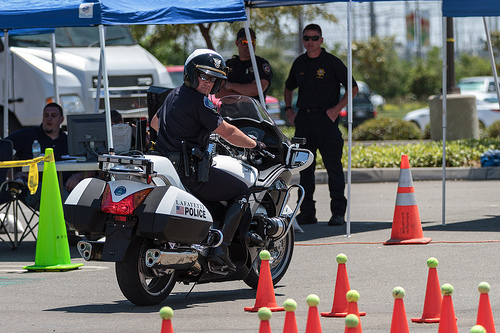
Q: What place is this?
A: It is a parking lot.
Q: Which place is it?
A: It is a parking lot.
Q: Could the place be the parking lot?
A: Yes, it is the parking lot.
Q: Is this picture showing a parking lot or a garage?
A: It is showing a parking lot.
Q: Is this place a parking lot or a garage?
A: It is a parking lot.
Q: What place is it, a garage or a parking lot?
A: It is a parking lot.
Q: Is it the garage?
A: No, it is the parking lot.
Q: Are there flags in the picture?
A: No, there are no flags.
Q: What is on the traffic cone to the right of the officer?
A: The tape is on the safety cone.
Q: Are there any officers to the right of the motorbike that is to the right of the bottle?
A: Yes, there is an officer to the right of the motorbike.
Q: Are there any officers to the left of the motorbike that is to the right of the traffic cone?
A: No, the officer is to the right of the motorbike.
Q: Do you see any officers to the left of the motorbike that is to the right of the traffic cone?
A: No, the officer is to the right of the motorbike.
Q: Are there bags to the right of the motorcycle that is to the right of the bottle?
A: No, there is an officer to the right of the motorbike.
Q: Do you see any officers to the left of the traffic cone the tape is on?
A: Yes, there is an officer to the left of the safety cone.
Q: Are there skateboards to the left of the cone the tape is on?
A: No, there is an officer to the left of the cone.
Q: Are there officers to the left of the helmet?
A: No, the officer is to the right of the helmet.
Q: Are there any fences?
A: No, there are no fences.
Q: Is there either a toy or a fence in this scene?
A: No, there are no fences or toys.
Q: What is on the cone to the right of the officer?
A: The tape is on the traffic cone.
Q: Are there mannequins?
A: No, there are no mannequins.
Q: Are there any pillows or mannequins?
A: No, there are no mannequins or pillows.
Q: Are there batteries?
A: No, there are no batteries.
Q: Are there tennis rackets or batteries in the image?
A: No, there are no batteries or tennis rackets.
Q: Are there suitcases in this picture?
A: No, there are no suitcases.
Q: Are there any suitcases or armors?
A: No, there are no suitcases or armors.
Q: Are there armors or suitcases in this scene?
A: No, there are no suitcases or armors.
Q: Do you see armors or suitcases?
A: No, there are no suitcases or armors.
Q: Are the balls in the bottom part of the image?
A: Yes, the balls are in the bottom of the image.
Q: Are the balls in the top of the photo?
A: No, the balls are in the bottom of the image.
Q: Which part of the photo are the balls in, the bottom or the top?
A: The balls are in the bottom of the image.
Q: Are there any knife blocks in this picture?
A: No, there are no knife blocks.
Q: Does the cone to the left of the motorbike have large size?
A: Yes, the cone is large.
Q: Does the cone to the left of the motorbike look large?
A: Yes, the cone is large.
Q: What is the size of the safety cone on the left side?
A: The cone is large.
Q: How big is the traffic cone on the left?
A: The cone is large.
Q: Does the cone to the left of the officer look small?
A: No, the traffic cone is large.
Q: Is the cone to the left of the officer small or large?
A: The traffic cone is large.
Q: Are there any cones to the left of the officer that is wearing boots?
A: Yes, there is a cone to the left of the officer.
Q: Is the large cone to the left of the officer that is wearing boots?
A: Yes, the traffic cone is to the left of the officer.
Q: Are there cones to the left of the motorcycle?
A: Yes, there is a cone to the left of the motorcycle.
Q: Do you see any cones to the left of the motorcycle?
A: Yes, there is a cone to the left of the motorcycle.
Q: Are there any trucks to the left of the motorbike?
A: No, there is a cone to the left of the motorbike.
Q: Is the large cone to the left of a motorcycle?
A: Yes, the traffic cone is to the left of a motorcycle.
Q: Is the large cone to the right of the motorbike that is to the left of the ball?
A: No, the cone is to the left of the motorbike.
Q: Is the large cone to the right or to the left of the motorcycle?
A: The cone is to the left of the motorcycle.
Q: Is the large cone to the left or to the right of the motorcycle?
A: The cone is to the left of the motorcycle.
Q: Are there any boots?
A: Yes, there are boots.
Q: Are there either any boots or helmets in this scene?
A: Yes, there are boots.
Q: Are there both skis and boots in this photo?
A: No, there are boots but no skis.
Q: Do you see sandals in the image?
A: No, there are no sandals.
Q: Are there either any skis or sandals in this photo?
A: No, there are no sandals or skis.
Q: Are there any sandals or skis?
A: No, there are no sandals or skis.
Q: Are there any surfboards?
A: No, there are no surfboards.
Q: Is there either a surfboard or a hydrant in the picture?
A: No, there are no surfboards or fire hydrants.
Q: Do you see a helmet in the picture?
A: Yes, there is a helmet.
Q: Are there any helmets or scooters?
A: Yes, there is a helmet.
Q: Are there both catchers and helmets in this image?
A: No, there is a helmet but no catchers.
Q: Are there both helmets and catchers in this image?
A: No, there is a helmet but no catchers.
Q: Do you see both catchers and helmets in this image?
A: No, there is a helmet but no catchers.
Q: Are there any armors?
A: No, there are no armors.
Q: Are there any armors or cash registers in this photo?
A: No, there are no armors or cash registers.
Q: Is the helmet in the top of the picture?
A: Yes, the helmet is in the top of the image.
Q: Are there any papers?
A: No, there are no papers.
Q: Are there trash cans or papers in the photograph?
A: No, there are no papers or trash cans.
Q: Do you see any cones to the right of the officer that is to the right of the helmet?
A: Yes, there is a cone to the right of the officer.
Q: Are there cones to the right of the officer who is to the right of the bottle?
A: Yes, there is a cone to the right of the officer.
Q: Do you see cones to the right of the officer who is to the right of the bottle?
A: Yes, there is a cone to the right of the officer.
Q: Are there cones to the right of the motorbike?
A: Yes, there is a cone to the right of the motorbike.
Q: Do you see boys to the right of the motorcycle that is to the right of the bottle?
A: No, there is a cone to the right of the motorbike.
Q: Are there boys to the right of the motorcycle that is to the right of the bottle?
A: No, there is a cone to the right of the motorbike.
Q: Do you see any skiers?
A: No, there are no skiers.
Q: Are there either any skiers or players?
A: No, there are no skiers or players.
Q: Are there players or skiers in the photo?
A: No, there are no skiers or players.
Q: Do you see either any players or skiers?
A: No, there are no skiers or players.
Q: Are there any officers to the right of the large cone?
A: Yes, there is an officer to the right of the traffic cone.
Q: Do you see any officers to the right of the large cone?
A: Yes, there is an officer to the right of the traffic cone.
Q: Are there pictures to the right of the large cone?
A: No, there is an officer to the right of the traffic cone.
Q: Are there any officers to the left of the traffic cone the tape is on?
A: Yes, there is an officer to the left of the safety cone.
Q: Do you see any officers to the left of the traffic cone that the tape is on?
A: Yes, there is an officer to the left of the safety cone.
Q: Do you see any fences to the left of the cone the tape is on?
A: No, there is an officer to the left of the traffic cone.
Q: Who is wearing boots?
A: The officer is wearing boots.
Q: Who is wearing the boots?
A: The officer is wearing boots.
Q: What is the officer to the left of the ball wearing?
A: The officer is wearing boots.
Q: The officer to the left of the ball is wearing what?
A: The officer is wearing boots.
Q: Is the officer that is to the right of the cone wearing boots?
A: Yes, the officer is wearing boots.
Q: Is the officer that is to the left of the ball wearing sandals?
A: No, the officer is wearing boots.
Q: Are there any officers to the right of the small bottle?
A: Yes, there is an officer to the right of the bottle.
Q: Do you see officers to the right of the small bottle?
A: Yes, there is an officer to the right of the bottle.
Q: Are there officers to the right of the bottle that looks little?
A: Yes, there is an officer to the right of the bottle.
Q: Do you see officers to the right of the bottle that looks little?
A: Yes, there is an officer to the right of the bottle.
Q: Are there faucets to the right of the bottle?
A: No, there is an officer to the right of the bottle.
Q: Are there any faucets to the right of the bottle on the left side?
A: No, there is an officer to the right of the bottle.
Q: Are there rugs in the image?
A: No, there are no rugs.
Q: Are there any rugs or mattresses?
A: No, there are no rugs or mattresses.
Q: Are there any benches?
A: No, there are no benches.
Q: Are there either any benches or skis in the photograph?
A: No, there are no benches or skis.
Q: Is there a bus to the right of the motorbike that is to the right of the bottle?
A: No, there is a cone to the right of the motorbike.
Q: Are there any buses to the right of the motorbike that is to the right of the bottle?
A: No, there is a cone to the right of the motorbike.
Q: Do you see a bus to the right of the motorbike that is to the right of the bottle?
A: No, there is a cone to the right of the motorbike.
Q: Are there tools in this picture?
A: No, there are no tools.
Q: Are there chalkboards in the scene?
A: No, there are no chalkboards.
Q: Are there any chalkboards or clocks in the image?
A: No, there are no chalkboards or clocks.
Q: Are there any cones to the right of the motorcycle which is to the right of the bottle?
A: Yes, there is a cone to the right of the motorcycle.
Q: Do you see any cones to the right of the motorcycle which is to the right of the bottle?
A: Yes, there is a cone to the right of the motorcycle.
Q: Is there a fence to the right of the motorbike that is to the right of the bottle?
A: No, there is a cone to the right of the motorbike.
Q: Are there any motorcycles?
A: Yes, there is a motorcycle.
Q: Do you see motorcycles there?
A: Yes, there is a motorcycle.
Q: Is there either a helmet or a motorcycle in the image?
A: Yes, there is a motorcycle.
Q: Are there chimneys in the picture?
A: No, there are no chimneys.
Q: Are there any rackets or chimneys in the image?
A: No, there are no chimneys or rackets.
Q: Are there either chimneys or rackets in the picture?
A: No, there are no chimneys or rackets.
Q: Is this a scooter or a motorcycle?
A: This is a motorcycle.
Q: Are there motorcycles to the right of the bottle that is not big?
A: Yes, there is a motorcycle to the right of the bottle.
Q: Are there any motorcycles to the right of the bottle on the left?
A: Yes, there is a motorcycle to the right of the bottle.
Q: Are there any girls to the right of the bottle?
A: No, there is a motorcycle to the right of the bottle.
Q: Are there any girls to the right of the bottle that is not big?
A: No, there is a motorcycle to the right of the bottle.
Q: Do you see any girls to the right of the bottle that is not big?
A: No, there is a motorcycle to the right of the bottle.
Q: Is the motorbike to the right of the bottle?
A: Yes, the motorbike is to the right of the bottle.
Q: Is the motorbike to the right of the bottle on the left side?
A: Yes, the motorbike is to the right of the bottle.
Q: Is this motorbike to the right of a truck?
A: No, the motorbike is to the right of the bottle.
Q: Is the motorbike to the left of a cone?
A: Yes, the motorbike is to the left of a cone.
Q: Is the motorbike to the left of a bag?
A: No, the motorbike is to the left of a cone.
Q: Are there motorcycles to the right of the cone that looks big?
A: Yes, there is a motorcycle to the right of the traffic cone.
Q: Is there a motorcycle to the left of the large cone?
A: No, the motorcycle is to the right of the cone.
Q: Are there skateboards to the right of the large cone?
A: No, there is a motorcycle to the right of the traffic cone.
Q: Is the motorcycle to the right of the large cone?
A: Yes, the motorcycle is to the right of the cone.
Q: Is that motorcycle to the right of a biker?
A: No, the motorcycle is to the right of the cone.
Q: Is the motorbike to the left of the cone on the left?
A: No, the motorbike is to the right of the traffic cone.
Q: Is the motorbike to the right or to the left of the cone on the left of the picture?
A: The motorbike is to the right of the cone.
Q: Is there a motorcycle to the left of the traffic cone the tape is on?
A: Yes, there is a motorcycle to the left of the cone.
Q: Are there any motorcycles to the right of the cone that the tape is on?
A: No, the motorcycle is to the left of the traffic cone.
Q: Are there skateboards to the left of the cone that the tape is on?
A: No, there is a motorcycle to the left of the safety cone.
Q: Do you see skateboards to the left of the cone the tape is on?
A: No, there is a motorcycle to the left of the safety cone.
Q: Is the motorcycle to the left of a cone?
A: Yes, the motorcycle is to the left of a cone.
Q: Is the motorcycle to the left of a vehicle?
A: No, the motorcycle is to the left of a cone.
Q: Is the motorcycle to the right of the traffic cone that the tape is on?
A: No, the motorcycle is to the left of the cone.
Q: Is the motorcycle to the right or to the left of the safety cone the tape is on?
A: The motorcycle is to the left of the traffic cone.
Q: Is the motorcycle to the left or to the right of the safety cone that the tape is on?
A: The motorcycle is to the left of the traffic cone.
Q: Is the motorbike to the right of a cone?
A: No, the motorbike is to the left of a cone.